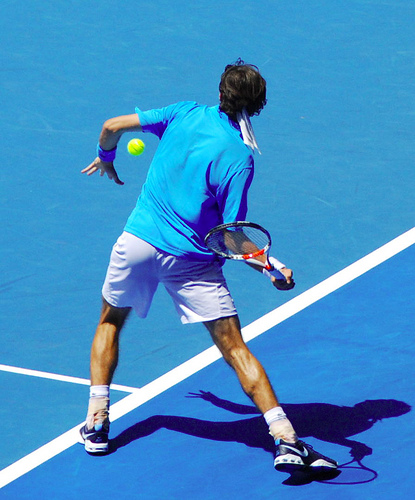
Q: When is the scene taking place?
A: Daytime.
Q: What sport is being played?
A: Tennis.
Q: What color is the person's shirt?
A: Blue.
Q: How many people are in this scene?
A: One.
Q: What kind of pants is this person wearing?
A: Shorts.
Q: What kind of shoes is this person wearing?
A: Sneakers.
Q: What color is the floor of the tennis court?
A: Blue.